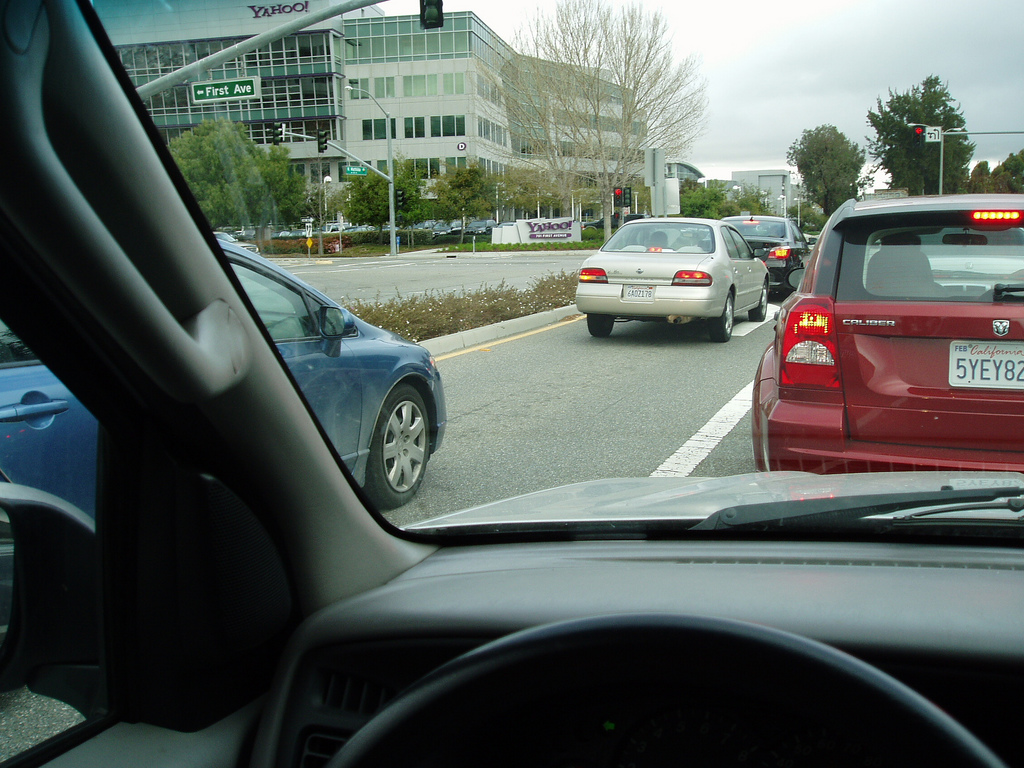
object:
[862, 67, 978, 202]
tree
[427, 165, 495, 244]
tree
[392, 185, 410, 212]
street light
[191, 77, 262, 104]
street sign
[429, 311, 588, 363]
line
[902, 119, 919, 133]
street light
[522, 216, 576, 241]
sign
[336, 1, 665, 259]
building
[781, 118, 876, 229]
tree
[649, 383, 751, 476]
line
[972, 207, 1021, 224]
mini lights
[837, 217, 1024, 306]
windshield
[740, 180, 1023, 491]
car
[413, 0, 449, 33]
light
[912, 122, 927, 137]
light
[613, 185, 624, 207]
light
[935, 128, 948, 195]
pole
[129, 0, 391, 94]
pole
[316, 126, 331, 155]
light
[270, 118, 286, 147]
light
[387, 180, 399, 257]
pole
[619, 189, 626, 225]
pole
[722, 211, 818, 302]
car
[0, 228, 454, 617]
car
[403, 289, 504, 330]
weeds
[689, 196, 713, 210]
leaves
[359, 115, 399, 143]
window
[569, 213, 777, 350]
car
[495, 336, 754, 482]
street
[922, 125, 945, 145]
traffic sign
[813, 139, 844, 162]
leaves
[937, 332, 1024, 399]
license plate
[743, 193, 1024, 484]
cars